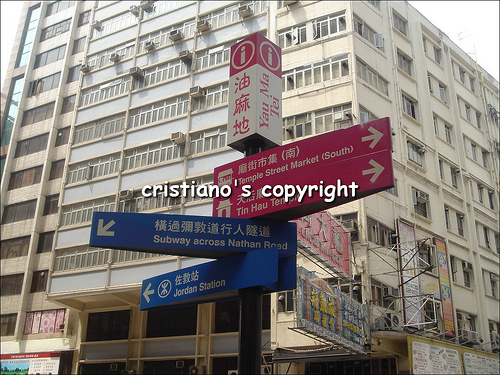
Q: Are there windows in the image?
A: Yes, there are windows.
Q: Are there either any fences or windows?
A: Yes, there are windows.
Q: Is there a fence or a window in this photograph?
A: Yes, there are windows.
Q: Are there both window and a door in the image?
A: No, there are windows but no doors.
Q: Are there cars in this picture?
A: No, there are no cars.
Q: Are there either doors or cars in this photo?
A: No, there are no cars or doors.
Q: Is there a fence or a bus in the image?
A: No, there are no buses or fences.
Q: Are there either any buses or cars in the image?
A: No, there are no cars or buses.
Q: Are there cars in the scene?
A: No, there are no cars.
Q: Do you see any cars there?
A: No, there are no cars.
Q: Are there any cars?
A: No, there are no cars.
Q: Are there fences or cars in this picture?
A: No, there are no cars or fences.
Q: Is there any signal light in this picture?
A: No, there are no traffic lights.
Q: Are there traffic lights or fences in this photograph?
A: No, there are no traffic lights or fences.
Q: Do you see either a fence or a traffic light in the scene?
A: No, there are no traffic lights or fences.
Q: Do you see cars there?
A: No, there are no cars.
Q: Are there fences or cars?
A: No, there are no cars or fences.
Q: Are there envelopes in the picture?
A: No, there are no envelopes.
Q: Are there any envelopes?
A: No, there are no envelopes.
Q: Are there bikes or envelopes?
A: No, there are no envelopes or bikes.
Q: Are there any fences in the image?
A: No, there are no fences.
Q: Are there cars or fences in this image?
A: No, there are no fences or cars.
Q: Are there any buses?
A: No, there are no buses.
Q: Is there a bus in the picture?
A: No, there are no buses.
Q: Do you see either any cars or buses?
A: No, there are no buses or cars.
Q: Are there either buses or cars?
A: No, there are no buses or cars.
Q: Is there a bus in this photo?
A: No, there are no buses.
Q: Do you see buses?
A: No, there are no buses.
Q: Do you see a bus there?
A: No, there are no buses.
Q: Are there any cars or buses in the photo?
A: No, there are no buses or cars.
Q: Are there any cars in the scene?
A: No, there are no cars.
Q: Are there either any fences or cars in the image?
A: No, there are no cars or fences.